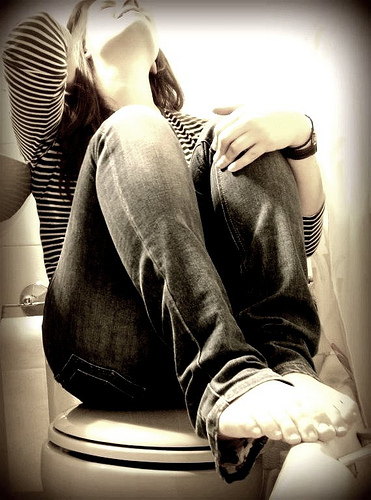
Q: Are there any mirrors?
A: No, there are no mirrors.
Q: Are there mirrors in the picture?
A: No, there are no mirrors.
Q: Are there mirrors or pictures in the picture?
A: No, there are no mirrors or pictures.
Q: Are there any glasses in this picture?
A: No, there are no glasses.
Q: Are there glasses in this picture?
A: No, there are no glasses.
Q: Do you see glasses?
A: No, there are no glasses.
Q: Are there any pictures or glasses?
A: No, there are no glasses or pictures.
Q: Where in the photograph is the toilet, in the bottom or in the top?
A: The toilet is in the bottom of the image.